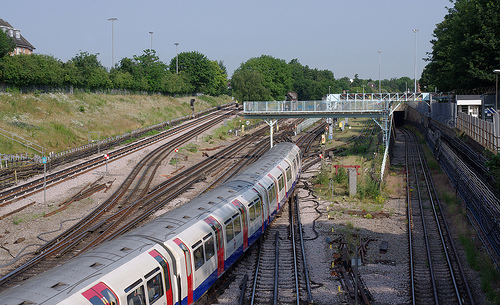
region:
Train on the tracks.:
[147, 114, 332, 258]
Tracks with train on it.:
[237, 120, 358, 272]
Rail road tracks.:
[221, 204, 365, 299]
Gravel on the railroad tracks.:
[249, 226, 326, 296]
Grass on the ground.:
[328, 147, 418, 266]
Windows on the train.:
[201, 212, 268, 268]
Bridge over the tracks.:
[236, 67, 486, 187]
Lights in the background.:
[82, 12, 197, 87]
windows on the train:
[191, 238, 226, 260]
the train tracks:
[252, 278, 298, 298]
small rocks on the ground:
[375, 266, 395, 293]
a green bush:
[187, 57, 216, 84]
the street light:
[105, 16, 117, 28]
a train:
[160, 205, 238, 279]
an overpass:
[240, 100, 402, 110]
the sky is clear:
[273, 10, 372, 51]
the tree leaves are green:
[438, 29, 498, 67]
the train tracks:
[407, 251, 451, 286]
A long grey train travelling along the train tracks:
[79, 143, 309, 303]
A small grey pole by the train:
[347, 165, 364, 192]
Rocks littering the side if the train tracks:
[306, 240, 333, 303]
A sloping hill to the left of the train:
[0, 66, 205, 168]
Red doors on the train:
[204, 213, 231, 275]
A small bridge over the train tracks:
[235, 85, 492, 132]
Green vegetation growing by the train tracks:
[362, 177, 386, 207]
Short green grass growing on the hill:
[19, 100, 79, 147]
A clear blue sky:
[213, 6, 378, 58]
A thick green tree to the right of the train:
[427, 5, 499, 95]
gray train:
[60, 138, 328, 303]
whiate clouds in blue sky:
[67, 13, 112, 48]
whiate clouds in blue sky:
[330, 26, 381, 54]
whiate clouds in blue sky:
[390, 13, 412, 54]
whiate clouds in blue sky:
[300, 18, 337, 55]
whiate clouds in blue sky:
[234, 11, 275, 38]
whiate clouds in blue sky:
[288, 22, 328, 50]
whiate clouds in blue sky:
[200, 9, 265, 33]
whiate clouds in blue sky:
[167, 15, 228, 57]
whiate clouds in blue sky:
[104, 13, 172, 43]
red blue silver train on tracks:
[17, 108, 306, 304]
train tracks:
[68, 120, 168, 192]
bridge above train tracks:
[230, 90, 428, 180]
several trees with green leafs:
[55, 50, 166, 96]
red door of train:
[197, 216, 237, 281]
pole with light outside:
[170, 26, 183, 75]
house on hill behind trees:
[0, 13, 50, 94]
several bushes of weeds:
[365, 173, 385, 200]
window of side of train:
[212, 210, 248, 244]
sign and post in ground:
[38, 152, 51, 208]